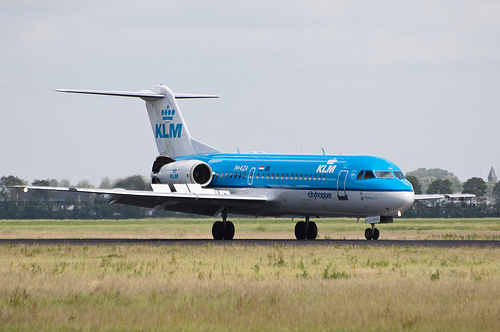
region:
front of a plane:
[348, 142, 435, 244]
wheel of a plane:
[360, 221, 387, 244]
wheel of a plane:
[283, 222, 325, 245]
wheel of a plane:
[208, 207, 248, 237]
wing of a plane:
[2, 162, 148, 208]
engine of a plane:
[146, 147, 217, 197]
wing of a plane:
[50, 68, 130, 128]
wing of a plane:
[185, 88, 227, 105]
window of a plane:
[230, 157, 337, 188]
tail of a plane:
[128, 101, 210, 156]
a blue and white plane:
[20, 71, 488, 277]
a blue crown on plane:
[156, 102, 181, 137]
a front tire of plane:
[358, 219, 409, 243]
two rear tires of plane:
[184, 201, 344, 251]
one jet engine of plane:
[146, 149, 217, 199]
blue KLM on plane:
[154, 120, 181, 145]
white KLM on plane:
[307, 154, 335, 182]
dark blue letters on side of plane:
[301, 180, 342, 207]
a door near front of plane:
[331, 156, 369, 227]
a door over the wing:
[237, 162, 266, 201]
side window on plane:
[218, 166, 227, 186]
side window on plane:
[220, 165, 243, 192]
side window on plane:
[222, 166, 234, 186]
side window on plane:
[232, 170, 244, 182]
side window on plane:
[250, 170, 266, 187]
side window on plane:
[267, 166, 287, 196]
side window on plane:
[280, 160, 290, 179]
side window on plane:
[293, 167, 310, 189]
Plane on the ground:
[10, 75, 480, 256]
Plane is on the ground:
[6, 82, 482, 251]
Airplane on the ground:
[8, 81, 478, 246]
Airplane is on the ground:
[6, 80, 478, 253]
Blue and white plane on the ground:
[5, 79, 480, 256]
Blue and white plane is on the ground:
[5, 79, 480, 250]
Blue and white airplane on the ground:
[7, 81, 480, 248]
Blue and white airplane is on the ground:
[6, 82, 477, 253]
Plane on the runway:
[9, 80, 480, 247]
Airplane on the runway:
[7, 81, 479, 256]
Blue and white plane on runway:
[53, 86, 476, 238]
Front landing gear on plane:
[360, 225, 380, 238]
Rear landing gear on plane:
[209, 220, 323, 239]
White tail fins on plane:
[62, 84, 223, 102]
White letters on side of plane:
[310, 160, 338, 174]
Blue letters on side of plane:
[303, 185, 333, 198]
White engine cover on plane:
[155, 159, 217, 186]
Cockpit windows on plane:
[357, 168, 403, 178]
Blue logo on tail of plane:
[158, 105, 176, 121]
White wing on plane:
[15, 183, 266, 200]